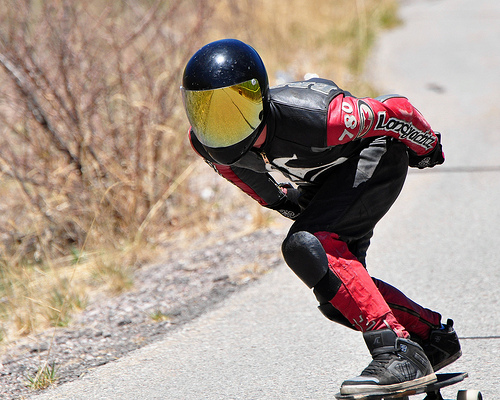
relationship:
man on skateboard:
[175, 47, 435, 262] [348, 382, 474, 398]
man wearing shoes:
[175, 47, 435, 262] [373, 335, 424, 377]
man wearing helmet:
[175, 47, 435, 262] [184, 56, 270, 159]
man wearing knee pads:
[175, 47, 435, 262] [282, 229, 343, 289]